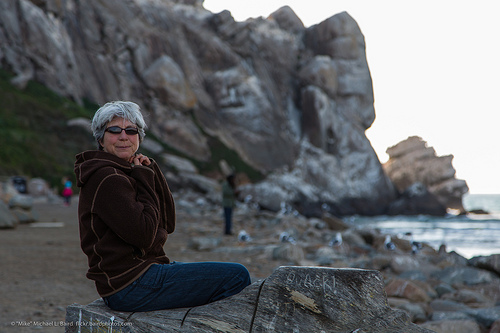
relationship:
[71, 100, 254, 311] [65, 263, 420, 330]
woman sitting on top of a rock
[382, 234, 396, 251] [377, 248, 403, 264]
seagull on top of rock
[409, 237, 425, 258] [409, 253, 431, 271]
seagull on top of rock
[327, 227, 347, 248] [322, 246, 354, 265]
seagull sitting on top of a rock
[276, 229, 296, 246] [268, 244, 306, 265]
seagull on top of a rock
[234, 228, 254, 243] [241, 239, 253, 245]
seagull sitting on top of a rock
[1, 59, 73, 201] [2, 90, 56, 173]
slope covered in vegetation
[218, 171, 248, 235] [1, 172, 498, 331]
person standing on beach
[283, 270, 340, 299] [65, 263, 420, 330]
"quack" carved into rock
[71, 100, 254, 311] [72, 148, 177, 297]
woman wearing a jacket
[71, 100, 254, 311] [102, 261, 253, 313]
woman has on blue jeans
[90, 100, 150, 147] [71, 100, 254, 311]
hair of lady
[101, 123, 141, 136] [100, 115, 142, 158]
sunglasses on face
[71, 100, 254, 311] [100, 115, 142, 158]
woman has a face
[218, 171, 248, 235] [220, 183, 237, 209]
person in a green jacket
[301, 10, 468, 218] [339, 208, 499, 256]
big rock formatons in water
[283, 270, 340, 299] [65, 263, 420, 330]
saying on rock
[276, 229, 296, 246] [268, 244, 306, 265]
bird on top of rock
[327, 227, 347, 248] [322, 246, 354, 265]
bird on top of rock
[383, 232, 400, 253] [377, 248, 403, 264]
bird on top of rock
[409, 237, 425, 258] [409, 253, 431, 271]
bird on top of rock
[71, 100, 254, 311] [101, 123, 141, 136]
woman wearing glasses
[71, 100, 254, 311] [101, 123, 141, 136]
woman wearing sun glasses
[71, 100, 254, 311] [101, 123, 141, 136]
woman wearing dark shades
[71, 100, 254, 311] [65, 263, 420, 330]
woman sitting down on a tree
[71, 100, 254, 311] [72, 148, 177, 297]
woman wearing a hoodie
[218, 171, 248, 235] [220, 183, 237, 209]
person wearing a coat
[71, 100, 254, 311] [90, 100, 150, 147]
woman with hair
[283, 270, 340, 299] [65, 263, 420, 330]
"quack" written on rock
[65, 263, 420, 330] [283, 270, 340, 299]
rock engraved with quack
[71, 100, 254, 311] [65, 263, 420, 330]
woman sitting on top of rock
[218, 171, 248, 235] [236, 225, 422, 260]
man feeding ducks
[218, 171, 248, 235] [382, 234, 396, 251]
man feeding duck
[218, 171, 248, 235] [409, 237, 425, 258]
man feeding duck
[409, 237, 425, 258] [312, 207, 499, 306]
duck around a shoreline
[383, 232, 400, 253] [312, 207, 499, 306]
duck around a shoreline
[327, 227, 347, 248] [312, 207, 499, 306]
duck around a shoreline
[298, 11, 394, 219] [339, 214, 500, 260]
large rock formation overlook shore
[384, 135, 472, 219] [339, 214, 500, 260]
large rock formation overlook shore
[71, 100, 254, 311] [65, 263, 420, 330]
elderly woman rests on top of a rock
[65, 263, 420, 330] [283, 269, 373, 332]
rock has been vandalized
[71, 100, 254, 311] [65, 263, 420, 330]
happy woman sitting on top of a large rock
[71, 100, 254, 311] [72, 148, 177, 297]
older woman wearing a brown sweatshirt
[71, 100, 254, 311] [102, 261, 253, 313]
older woman wearing blue jeans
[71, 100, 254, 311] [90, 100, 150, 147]
older woman with short grey hair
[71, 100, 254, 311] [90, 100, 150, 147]
sitting woman with hair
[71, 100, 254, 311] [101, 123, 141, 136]
sitting woman with sunglasses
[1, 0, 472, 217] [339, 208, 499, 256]
rock landscape next to a lake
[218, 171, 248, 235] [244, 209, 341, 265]
dark person on a rocky shore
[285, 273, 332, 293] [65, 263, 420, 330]
"quack" carved in stone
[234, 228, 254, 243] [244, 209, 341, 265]
seagull on a rocky shore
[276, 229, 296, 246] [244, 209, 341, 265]
seagull on a rocky shore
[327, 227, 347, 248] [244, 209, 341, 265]
seagull on a rocky shore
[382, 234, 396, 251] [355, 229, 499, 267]
seagull on a rocky shore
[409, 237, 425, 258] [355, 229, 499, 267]
seagull on a rocky shore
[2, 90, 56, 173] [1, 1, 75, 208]
grass area in rock landscape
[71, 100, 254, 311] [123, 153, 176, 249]
happy woman with arms folded